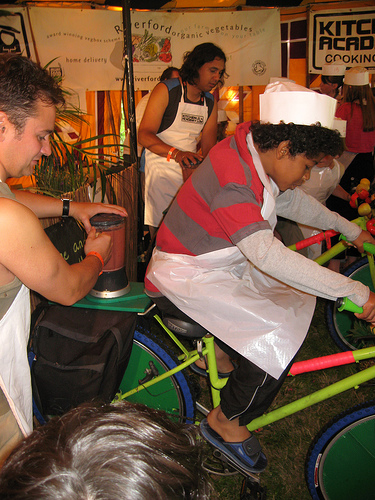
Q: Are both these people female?
A: No, they are both male and female.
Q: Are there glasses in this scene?
A: No, there are no glasses.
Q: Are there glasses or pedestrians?
A: No, there are no glasses or pedestrians.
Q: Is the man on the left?
A: Yes, the man is on the left of the image.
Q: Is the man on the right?
A: No, the man is on the left of the image.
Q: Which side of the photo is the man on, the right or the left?
A: The man is on the left of the image.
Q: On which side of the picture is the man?
A: The man is on the left of the image.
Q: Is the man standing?
A: Yes, the man is standing.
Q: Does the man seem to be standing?
A: Yes, the man is standing.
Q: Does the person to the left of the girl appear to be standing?
A: Yes, the man is standing.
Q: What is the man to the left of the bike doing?
A: The man is standing.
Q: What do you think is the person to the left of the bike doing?
A: The man is standing.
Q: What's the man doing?
A: The man is standing.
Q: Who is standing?
A: The man is standing.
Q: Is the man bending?
A: No, the man is standing.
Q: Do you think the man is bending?
A: No, the man is standing.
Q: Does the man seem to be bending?
A: No, the man is standing.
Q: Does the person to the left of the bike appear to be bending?
A: No, the man is standing.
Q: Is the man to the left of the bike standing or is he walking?
A: The man is standing.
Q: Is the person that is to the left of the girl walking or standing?
A: The man is standing.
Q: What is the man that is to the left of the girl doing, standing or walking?
A: The man is standing.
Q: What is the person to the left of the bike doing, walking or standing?
A: The man is standing.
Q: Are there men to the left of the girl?
A: Yes, there is a man to the left of the girl.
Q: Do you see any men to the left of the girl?
A: Yes, there is a man to the left of the girl.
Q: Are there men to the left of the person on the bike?
A: Yes, there is a man to the left of the girl.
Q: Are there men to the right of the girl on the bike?
A: No, the man is to the left of the girl.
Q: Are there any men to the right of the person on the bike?
A: No, the man is to the left of the girl.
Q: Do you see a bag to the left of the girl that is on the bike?
A: No, there is a man to the left of the girl.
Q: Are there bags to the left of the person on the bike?
A: No, there is a man to the left of the girl.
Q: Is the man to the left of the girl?
A: Yes, the man is to the left of the girl.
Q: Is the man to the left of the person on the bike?
A: Yes, the man is to the left of the girl.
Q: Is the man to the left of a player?
A: No, the man is to the left of the girl.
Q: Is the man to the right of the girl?
A: No, the man is to the left of the girl.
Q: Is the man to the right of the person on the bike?
A: No, the man is to the left of the girl.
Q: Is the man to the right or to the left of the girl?
A: The man is to the left of the girl.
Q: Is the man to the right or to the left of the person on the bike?
A: The man is to the left of the girl.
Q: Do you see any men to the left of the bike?
A: Yes, there is a man to the left of the bike.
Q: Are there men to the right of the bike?
A: No, the man is to the left of the bike.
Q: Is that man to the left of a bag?
A: No, the man is to the left of the bike.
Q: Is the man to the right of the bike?
A: No, the man is to the left of the bike.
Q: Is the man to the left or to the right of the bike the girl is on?
A: The man is to the left of the bike.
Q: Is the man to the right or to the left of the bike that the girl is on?
A: The man is to the left of the bike.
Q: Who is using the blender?
A: The man is using the blender.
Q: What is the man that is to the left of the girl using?
A: The man is using a blender.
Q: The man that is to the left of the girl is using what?
A: The man is using a blender.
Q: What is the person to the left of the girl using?
A: The man is using a blender.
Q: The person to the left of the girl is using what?
A: The man is using a blender.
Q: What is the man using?
A: The man is using a blender.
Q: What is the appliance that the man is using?
A: The appliance is a blender.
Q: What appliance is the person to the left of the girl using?
A: The man is using a blender.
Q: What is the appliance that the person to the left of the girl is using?
A: The appliance is a blender.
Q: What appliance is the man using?
A: The man is using a blender.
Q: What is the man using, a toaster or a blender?
A: The man is using a blender.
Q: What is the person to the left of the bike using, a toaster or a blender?
A: The man is using a blender.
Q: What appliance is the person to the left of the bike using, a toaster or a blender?
A: The man is using a blender.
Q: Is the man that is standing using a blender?
A: Yes, the man is using a blender.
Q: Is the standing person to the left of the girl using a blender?
A: Yes, the man is using a blender.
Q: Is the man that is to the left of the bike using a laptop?
A: No, the man is using a blender.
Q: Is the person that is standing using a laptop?
A: No, the man is using a blender.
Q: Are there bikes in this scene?
A: Yes, there is a bike.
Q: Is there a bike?
A: Yes, there is a bike.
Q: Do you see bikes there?
A: Yes, there is a bike.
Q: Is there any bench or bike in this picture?
A: Yes, there is a bike.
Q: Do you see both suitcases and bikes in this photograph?
A: No, there is a bike but no suitcases.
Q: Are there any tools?
A: No, there are no tools.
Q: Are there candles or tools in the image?
A: No, there are no tools or candles.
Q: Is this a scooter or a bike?
A: This is a bike.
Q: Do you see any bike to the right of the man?
A: Yes, there is a bike to the right of the man.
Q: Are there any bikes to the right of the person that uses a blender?
A: Yes, there is a bike to the right of the man.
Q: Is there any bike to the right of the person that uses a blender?
A: Yes, there is a bike to the right of the man.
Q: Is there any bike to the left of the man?
A: No, the bike is to the right of the man.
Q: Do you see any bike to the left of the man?
A: No, the bike is to the right of the man.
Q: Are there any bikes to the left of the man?
A: No, the bike is to the right of the man.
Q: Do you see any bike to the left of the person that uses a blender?
A: No, the bike is to the right of the man.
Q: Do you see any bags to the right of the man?
A: No, there is a bike to the right of the man.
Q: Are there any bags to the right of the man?
A: No, there is a bike to the right of the man.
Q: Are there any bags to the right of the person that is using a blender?
A: No, there is a bike to the right of the man.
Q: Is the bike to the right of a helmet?
A: No, the bike is to the right of the man.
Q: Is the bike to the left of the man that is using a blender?
A: No, the bike is to the right of the man.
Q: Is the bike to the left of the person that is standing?
A: No, the bike is to the right of the man.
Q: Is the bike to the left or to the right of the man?
A: The bike is to the right of the man.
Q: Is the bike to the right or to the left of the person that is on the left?
A: The bike is to the right of the man.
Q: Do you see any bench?
A: No, there are no benches.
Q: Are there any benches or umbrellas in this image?
A: No, there are no benches or umbrellas.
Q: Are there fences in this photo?
A: No, there are no fences.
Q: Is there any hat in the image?
A: Yes, there is a hat.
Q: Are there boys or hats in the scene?
A: Yes, there is a hat.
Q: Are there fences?
A: No, there are no fences.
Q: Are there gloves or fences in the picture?
A: No, there are no fences or gloves.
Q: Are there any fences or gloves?
A: No, there are no fences or gloves.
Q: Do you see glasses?
A: No, there are no glasses.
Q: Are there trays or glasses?
A: No, there are no glasses or trays.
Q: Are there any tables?
A: Yes, there is a table.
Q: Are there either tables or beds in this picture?
A: Yes, there is a table.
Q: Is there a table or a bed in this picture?
A: Yes, there is a table.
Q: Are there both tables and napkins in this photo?
A: No, there is a table but no napkins.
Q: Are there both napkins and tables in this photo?
A: No, there is a table but no napkins.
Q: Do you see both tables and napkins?
A: No, there is a table but no napkins.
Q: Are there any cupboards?
A: No, there are no cupboards.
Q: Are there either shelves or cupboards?
A: No, there are no cupboards or shelves.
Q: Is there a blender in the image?
A: Yes, there is a blender.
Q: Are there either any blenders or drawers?
A: Yes, there is a blender.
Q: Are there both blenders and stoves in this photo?
A: No, there is a blender but no stoves.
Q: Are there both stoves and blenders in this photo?
A: No, there is a blender but no stoves.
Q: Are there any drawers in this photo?
A: No, there are no drawers.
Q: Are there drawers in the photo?
A: No, there are no drawers.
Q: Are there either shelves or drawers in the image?
A: No, there are no drawers or shelves.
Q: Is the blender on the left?
A: Yes, the blender is on the left of the image.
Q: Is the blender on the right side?
A: No, the blender is on the left of the image.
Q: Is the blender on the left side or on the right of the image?
A: The blender is on the left of the image.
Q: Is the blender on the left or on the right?
A: The blender is on the left of the image.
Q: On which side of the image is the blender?
A: The blender is on the left of the image.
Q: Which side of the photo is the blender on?
A: The blender is on the left of the image.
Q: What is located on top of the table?
A: The blender is on top of the table.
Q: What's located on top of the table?
A: The blender is on top of the table.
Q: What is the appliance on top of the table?
A: The appliance is a blender.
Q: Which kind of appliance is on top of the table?
A: The appliance is a blender.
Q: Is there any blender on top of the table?
A: Yes, there is a blender on top of the table.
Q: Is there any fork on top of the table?
A: No, there is a blender on top of the table.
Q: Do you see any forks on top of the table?
A: No, there is a blender on top of the table.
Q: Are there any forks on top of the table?
A: No, there is a blender on top of the table.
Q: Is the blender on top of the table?
A: Yes, the blender is on top of the table.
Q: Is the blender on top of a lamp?
A: No, the blender is on top of the table.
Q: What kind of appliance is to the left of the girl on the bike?
A: The appliance is a blender.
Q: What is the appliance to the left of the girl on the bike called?
A: The appliance is a blender.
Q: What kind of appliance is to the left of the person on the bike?
A: The appliance is a blender.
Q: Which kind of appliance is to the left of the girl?
A: The appliance is a blender.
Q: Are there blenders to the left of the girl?
A: Yes, there is a blender to the left of the girl.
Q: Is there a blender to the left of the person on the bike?
A: Yes, there is a blender to the left of the girl.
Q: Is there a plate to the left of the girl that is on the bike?
A: No, there is a blender to the left of the girl.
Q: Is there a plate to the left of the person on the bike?
A: No, there is a blender to the left of the girl.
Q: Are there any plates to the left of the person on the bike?
A: No, there is a blender to the left of the girl.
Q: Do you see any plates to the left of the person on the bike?
A: No, there is a blender to the left of the girl.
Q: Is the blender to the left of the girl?
A: Yes, the blender is to the left of the girl.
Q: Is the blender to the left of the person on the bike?
A: Yes, the blender is to the left of the girl.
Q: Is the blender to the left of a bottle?
A: No, the blender is to the left of the girl.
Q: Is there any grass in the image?
A: Yes, there is grass.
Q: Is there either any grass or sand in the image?
A: Yes, there is grass.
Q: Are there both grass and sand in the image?
A: No, there is grass but no sand.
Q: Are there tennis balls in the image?
A: No, there are no tennis balls.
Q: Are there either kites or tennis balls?
A: No, there are no tennis balls or kites.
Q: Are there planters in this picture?
A: No, there are no planters.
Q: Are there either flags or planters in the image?
A: No, there are no planters or flags.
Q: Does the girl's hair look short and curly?
A: Yes, the hair is short and curly.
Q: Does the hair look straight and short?
A: No, the hair is short but curly.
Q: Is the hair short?
A: Yes, the hair is short.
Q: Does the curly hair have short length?
A: Yes, the hair is short.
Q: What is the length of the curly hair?
A: The hair is short.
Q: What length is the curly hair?
A: The hair is short.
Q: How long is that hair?
A: The hair is short.